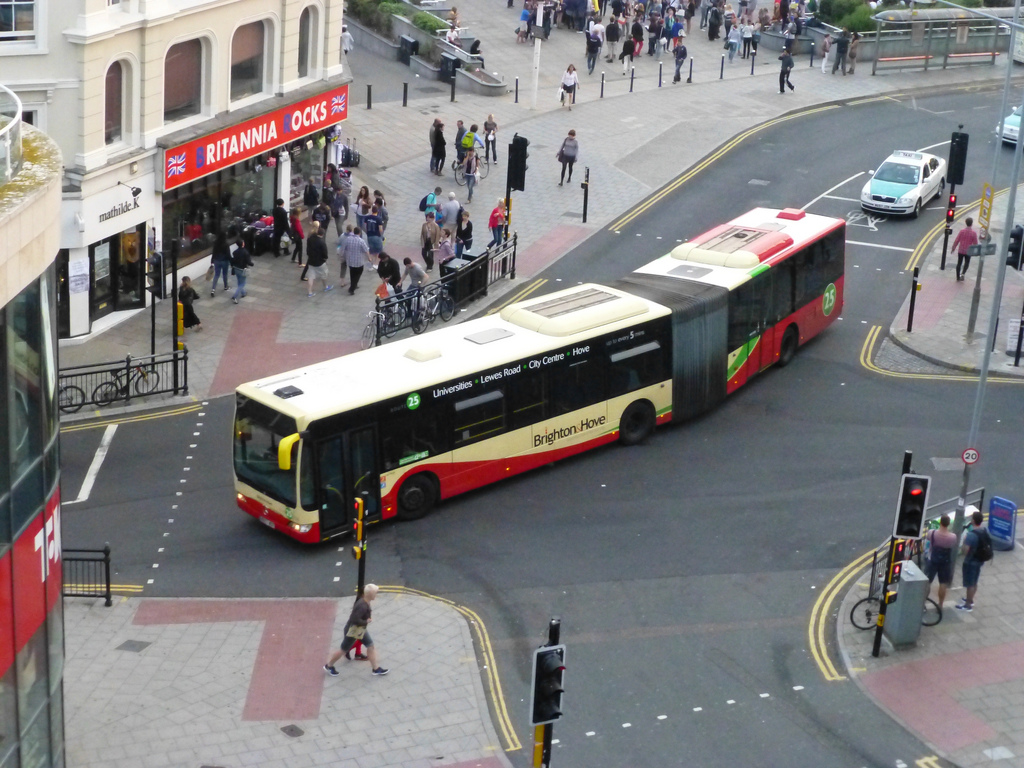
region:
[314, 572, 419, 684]
man about the cross the street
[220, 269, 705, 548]
front half of the big bus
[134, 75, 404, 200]
red sign of the store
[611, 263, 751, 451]
accordion part of the bus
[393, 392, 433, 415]
small green circle on the front half of the bus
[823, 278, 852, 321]
big green circle on the back of the bus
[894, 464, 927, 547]
red stop light on corner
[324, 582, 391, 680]
person walking on sidewalk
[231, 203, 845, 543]
bus turning onto new street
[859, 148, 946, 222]
taxi driving behind bus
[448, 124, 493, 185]
person riding a bike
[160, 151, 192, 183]
british flag on sign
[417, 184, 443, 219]
person wearing a blue shirt and backpack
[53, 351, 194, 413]
bikes on bike rack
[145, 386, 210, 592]
lines for cross walk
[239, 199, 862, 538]
a white and red extended bus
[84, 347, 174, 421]
a bike propped against a black fence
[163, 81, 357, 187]
a red sign with white letters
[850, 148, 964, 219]
a taxi behind the bus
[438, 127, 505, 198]
a person riding a bike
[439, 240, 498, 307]
two black trashcans by the fence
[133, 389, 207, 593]
a white dotted line on the road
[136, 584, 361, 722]
red bricks make a L on the sidewalk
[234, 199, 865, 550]
double long city bus accordianed in middle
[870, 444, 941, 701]
pole with traffic and crossing lights all red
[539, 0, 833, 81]
crowd of people in pedestrian only steet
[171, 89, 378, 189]
red sign reading BRITANNIA ROCKS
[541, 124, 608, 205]
a person on the sidewalk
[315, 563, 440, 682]
a person on the sidewalk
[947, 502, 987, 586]
a person on the sidewalk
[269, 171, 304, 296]
a person on the sidewalk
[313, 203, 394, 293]
a person on the sidewalk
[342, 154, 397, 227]
a person on the sidewalk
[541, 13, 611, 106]
a person on the sidewalk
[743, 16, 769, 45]
a person on the sidewalk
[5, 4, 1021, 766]
sky view of city street